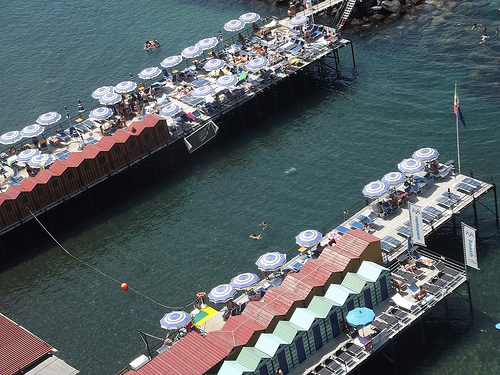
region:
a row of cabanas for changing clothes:
[2, 108, 179, 236]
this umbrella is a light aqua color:
[343, 306, 376, 340]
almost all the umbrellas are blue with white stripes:
[357, 140, 443, 203]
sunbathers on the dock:
[388, 273, 431, 303]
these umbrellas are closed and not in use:
[59, 96, 89, 123]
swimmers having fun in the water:
[244, 218, 273, 243]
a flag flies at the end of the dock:
[448, 79, 470, 178]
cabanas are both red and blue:
[213, 253, 394, 374]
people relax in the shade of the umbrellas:
[359, 143, 444, 220]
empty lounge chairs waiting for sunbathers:
[281, 23, 326, 55]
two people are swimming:
[231, 211, 287, 249]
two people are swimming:
[238, 212, 271, 242]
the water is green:
[178, 188, 233, 266]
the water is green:
[230, 158, 304, 203]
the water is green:
[127, 192, 239, 242]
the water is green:
[140, 198, 224, 268]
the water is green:
[123, 218, 225, 290]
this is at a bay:
[20, 34, 462, 343]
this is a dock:
[30, 77, 305, 217]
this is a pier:
[263, 225, 494, 347]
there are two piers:
[55, 84, 455, 351]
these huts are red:
[34, 172, 106, 192]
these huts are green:
[262, 322, 332, 348]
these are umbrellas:
[345, 141, 435, 185]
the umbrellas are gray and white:
[352, 172, 429, 212]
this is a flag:
[430, 67, 489, 156]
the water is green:
[152, 189, 287, 279]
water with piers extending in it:
[5, 14, 485, 360]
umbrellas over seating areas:
[352, 148, 452, 215]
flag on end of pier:
[450, 70, 484, 180]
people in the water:
[232, 208, 282, 244]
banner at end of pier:
[458, 224, 483, 268]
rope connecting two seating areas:
[28, 216, 192, 308]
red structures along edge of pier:
[5, 159, 96, 197]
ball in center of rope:
[116, 276, 136, 293]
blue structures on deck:
[321, 260, 388, 307]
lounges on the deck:
[458, 171, 480, 195]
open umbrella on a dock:
[365, 180, 385, 202]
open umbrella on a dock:
[340, 303, 382, 335]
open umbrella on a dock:
[254, 250, 290, 278]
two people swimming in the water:
[248, 216, 271, 246]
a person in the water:
[140, 36, 163, 56]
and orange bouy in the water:
[104, 261, 149, 307]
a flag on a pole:
[445, 74, 472, 181]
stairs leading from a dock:
[331, 1, 365, 31]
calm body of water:
[170, 193, 218, 239]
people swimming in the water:
[462, 21, 499, 47]